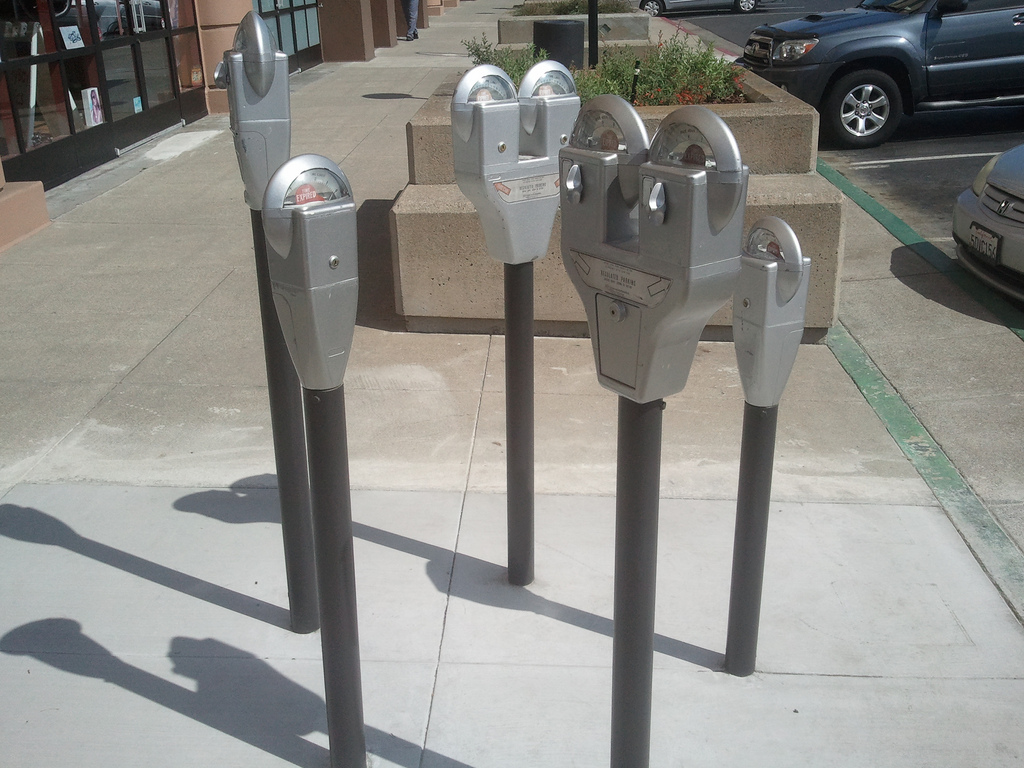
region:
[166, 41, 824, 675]
collection of parking meters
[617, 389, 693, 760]
black pole under meter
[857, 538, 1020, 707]
sidewalk is light grey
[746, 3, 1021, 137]
dark green truck is parked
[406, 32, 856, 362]
grey seat around plants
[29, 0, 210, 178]
black frame around doors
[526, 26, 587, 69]
black bin in distance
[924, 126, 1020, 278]
grey car on right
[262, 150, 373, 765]
Parking meter on a black post.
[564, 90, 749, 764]
Double parking meter on a black post.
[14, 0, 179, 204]
Windows on front of door.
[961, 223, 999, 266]
An automobile license plate.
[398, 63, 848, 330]
Concrete raised planter box.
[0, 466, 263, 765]
Shadows of parking meters.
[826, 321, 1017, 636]
Green line on sidewalk.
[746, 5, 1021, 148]
Front of a blue automobile.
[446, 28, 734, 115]
Green plants growing in raised box.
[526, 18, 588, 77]
A black colored trash can.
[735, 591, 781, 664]
pole on the sidewalk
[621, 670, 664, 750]
pole on the sidewalk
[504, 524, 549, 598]
pole on the sidewalk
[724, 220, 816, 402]
meter on the pole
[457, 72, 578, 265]
meter on the pole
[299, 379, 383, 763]
the long metal pole of the parking meter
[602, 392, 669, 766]
the long metal pole of the parking meter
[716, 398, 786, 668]
the long metal pole of the parking meter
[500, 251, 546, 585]
the long metal pole of the parking meter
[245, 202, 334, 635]
the long metal pole of the parking meter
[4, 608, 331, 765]
the shadow of the parking meter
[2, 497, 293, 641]
the shadow of the parking meter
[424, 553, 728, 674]
the shadow of the parking meter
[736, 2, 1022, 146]
A dark grey parked suv.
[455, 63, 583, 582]
Double light silver meter with black pole that has the most sun shining on it.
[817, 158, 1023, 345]
Green line in front of two parked cars.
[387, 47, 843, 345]
Large grey concrete flower bed past the meters.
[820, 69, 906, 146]
Front driver wheel on a grey suv.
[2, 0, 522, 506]
Long grey block sidewalk.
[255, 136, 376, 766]
silver parking meter on walk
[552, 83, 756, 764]
silver parking meter on walk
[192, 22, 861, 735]
a group of meters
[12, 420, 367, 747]
shadows on the ground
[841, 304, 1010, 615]
line on the sidewalk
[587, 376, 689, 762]
pole for the meter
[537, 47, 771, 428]
double sides on the meter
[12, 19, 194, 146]
a row of windows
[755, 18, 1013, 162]
car parked on the side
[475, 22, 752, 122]
plants in a planter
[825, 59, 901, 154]
tire on the car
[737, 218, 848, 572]
a parking meter on the sideawlk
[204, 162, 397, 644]
a parking meter on the sideawlk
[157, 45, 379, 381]
a parking meter on the sideawlk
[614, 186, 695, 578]
parking meter on the pole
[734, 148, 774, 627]
parking meter on the pole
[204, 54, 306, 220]
parking meter on the pole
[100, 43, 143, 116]
A window on a building.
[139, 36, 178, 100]
A window on a building.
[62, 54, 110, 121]
A window on a building.